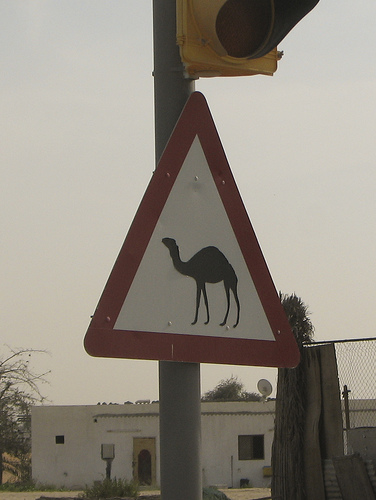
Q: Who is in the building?
A: Nobody.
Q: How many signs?
A: One.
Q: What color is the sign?
A: Red and white.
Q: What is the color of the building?
A: White and yellow door.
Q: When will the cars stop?
A: When the camel goes by.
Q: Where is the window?
A: On the building.